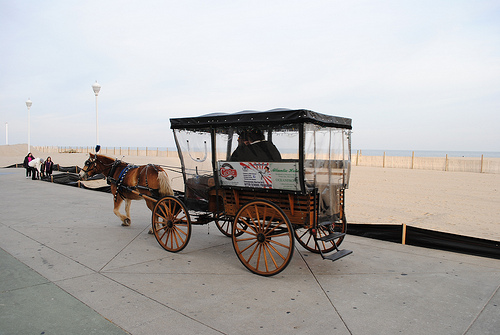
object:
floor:
[0, 165, 498, 334]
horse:
[77, 152, 172, 235]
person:
[231, 130, 280, 161]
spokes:
[261, 240, 270, 272]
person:
[44, 156, 54, 183]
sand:
[4, 142, 499, 244]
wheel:
[229, 200, 297, 277]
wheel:
[150, 198, 191, 252]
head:
[78, 152, 108, 181]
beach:
[2, 143, 499, 243]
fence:
[30, 144, 498, 174]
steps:
[327, 249, 352, 262]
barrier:
[345, 222, 499, 259]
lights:
[25, 96, 34, 161]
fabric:
[0, 161, 498, 259]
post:
[400, 221, 407, 245]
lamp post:
[94, 95, 99, 157]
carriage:
[149, 106, 352, 276]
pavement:
[0, 166, 500, 334]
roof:
[170, 107, 354, 128]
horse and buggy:
[76, 108, 353, 277]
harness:
[115, 164, 142, 192]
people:
[23, 152, 35, 176]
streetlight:
[91, 82, 101, 152]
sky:
[0, 0, 498, 149]